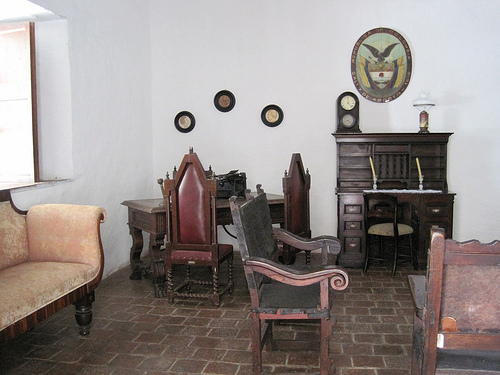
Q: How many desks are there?
A: Two.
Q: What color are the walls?
A: White.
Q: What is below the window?
A: A sofa.